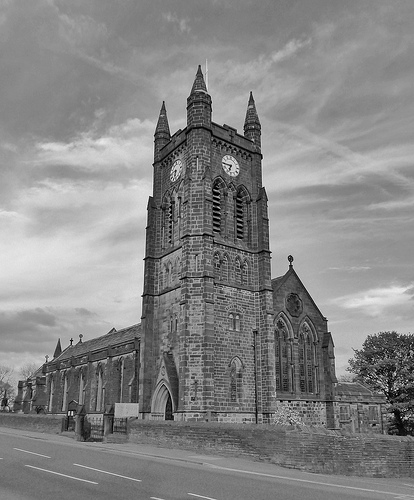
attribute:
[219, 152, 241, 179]
clock — old, white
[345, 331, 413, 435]
tree — bushy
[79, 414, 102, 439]
gate — metal, tall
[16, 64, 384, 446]
building — old, cathedal-style, tall, grey, large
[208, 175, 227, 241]
window — high arched, long, large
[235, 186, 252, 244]
window — high arched, long, large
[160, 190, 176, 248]
window — high arched, long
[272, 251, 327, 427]
building — short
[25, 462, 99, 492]
stripe — white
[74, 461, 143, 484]
stripe — white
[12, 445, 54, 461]
stripe — white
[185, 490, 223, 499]
stripe — white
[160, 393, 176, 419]
door — closed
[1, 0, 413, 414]
sky — dark